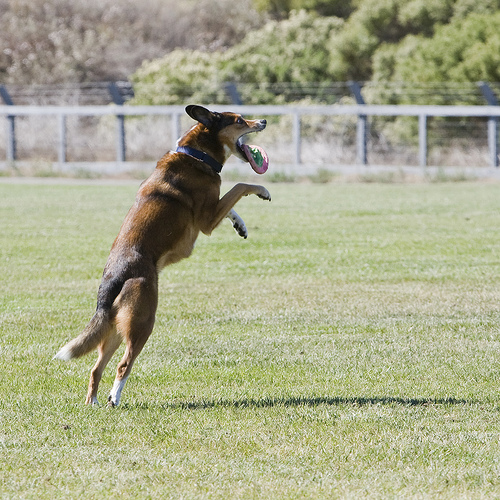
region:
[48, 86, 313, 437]
A brown, black and white dog.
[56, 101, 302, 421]
Dog catching something in his mouth.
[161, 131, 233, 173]
Blue collar around dog's neck.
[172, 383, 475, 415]
Shadow of dog on the ground.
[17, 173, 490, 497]
A large open field.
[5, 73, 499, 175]
A fence in the background.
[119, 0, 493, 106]
Green trees behind fence.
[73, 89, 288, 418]
Dog standing on hind legs.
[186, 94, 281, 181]
Dog's mouth is wide open.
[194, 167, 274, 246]
Dog's front legs.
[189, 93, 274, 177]
dog catching frisbee in mouth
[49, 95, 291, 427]
dog jumping in air to catch toy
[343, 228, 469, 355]
brown and green grass growing in the park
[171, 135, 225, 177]
navy blue fabric collar on dog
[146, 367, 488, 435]
shadow of dog being cast in grass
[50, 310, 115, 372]
furry tail on dog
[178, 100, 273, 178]
dog's head with popped ears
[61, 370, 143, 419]
back paws of the dog that it is standing on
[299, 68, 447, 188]
fence around enclosed dog park area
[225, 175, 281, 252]
front dog paws in the air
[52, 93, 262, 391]
brown dog catching toy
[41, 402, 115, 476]
short brown and green grass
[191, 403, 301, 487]
short brown and green grass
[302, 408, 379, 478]
short brown and green grass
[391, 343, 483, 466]
short brown and green grass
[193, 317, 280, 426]
short brown and green grass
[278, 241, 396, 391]
short brown and green grass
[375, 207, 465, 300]
short brown and green grass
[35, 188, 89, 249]
short brown and green grass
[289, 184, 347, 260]
short brown and green grass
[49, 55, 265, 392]
the dog is brown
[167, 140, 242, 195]
dog is wearing a collar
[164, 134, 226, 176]
dog is wearing a collar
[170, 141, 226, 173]
Dog wearing a collar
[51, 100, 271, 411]
Brown dog playing on the grass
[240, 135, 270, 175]
Dog catching a frisbee in its mouth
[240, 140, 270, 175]
Brown dog catching a frisbee in its mouth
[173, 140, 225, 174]
Brown dog wearing a collar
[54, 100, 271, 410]
Brown dog playing on grass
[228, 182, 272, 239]
Dog has white paws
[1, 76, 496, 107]
Barbed wire on fence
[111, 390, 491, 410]
Shadow of dog playing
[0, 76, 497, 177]
Barbed wire fence